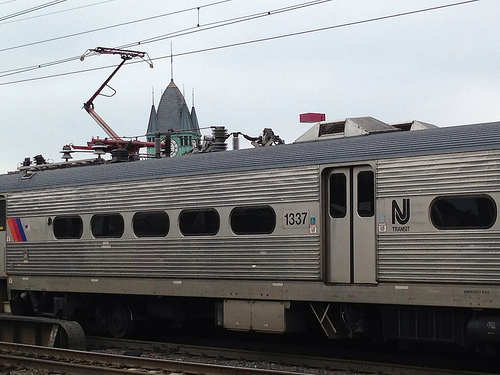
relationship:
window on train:
[87, 208, 127, 240] [0, 116, 499, 351]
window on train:
[130, 204, 171, 239] [0, 116, 499, 351]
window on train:
[179, 206, 222, 239] [0, 116, 499, 351]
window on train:
[230, 206, 278, 235] [0, 116, 499, 351]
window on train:
[427, 192, 500, 232] [0, 116, 499, 351]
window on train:
[230, 206, 278, 235] [1, 115, 499, 300]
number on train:
[285, 211, 308, 226] [0, 116, 499, 351]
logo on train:
[386, 192, 413, 232] [2, 115, 498, 324]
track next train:
[50, 323, 213, 373] [2, 115, 498, 324]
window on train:
[47, 210, 86, 242] [0, 116, 499, 351]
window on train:
[179, 206, 222, 239] [1, 115, 499, 300]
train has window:
[0, 116, 499, 351] [224, 194, 280, 239]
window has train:
[353, 163, 378, 221] [0, 116, 499, 351]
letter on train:
[388, 223, 413, 235] [0, 116, 499, 351]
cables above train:
[0, 0, 474, 89] [0, 116, 499, 351]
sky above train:
[2, 6, 498, 131] [0, 116, 499, 351]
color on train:
[5, 216, 18, 243] [0, 116, 499, 351]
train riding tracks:
[0, 116, 499, 351] [27, 318, 482, 373]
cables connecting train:
[9, 4, 355, 83] [0, 116, 499, 351]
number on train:
[285, 203, 320, 235] [153, 185, 357, 244]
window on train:
[230, 206, 278, 235] [54, 166, 464, 320]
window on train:
[427, 192, 500, 232] [52, 153, 379, 299]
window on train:
[230, 206, 278, 235] [11, 153, 470, 353]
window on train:
[232, 208, 277, 227] [4, 96, 484, 336]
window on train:
[230, 206, 278, 235] [27, 112, 475, 315]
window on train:
[401, 174, 481, 254] [29, 92, 465, 332]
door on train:
[316, 156, 379, 289] [40, 109, 481, 365]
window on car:
[353, 163, 376, 218] [33, 116, 353, 361]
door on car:
[316, 150, 387, 327] [22, 103, 310, 316]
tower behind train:
[129, 56, 216, 186] [15, 114, 476, 338]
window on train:
[157, 173, 217, 269] [40, 109, 481, 365]